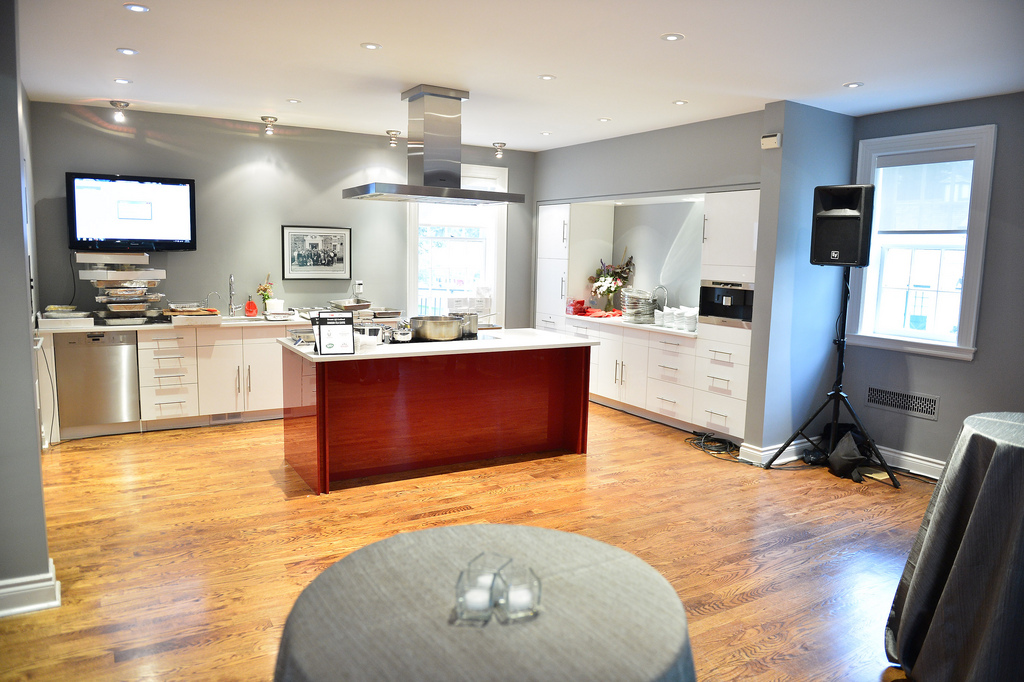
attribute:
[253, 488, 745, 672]
table — gray 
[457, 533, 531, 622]
candles — white 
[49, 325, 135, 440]
dishwasher — silver 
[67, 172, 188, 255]
screen — large 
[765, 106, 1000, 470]
wall — grey 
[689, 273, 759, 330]
microwave — built in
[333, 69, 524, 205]
fan — exhaust, over stove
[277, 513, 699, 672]
cloth — grey 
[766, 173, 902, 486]
speaker — black 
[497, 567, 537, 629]
holder — square 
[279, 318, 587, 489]
island — wood , marble 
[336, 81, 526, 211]
vent — silver 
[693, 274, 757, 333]
microwave — silver 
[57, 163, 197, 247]
screen — black 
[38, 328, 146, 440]
washer — silver 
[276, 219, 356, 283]
painting — black , white 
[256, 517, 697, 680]
table — round, grey 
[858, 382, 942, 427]
wall — grey 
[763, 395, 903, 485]
stand — black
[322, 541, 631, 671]
table — round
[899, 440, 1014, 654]
tablecloth — grey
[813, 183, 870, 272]
speaker — black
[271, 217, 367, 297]
frame — black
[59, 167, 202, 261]
tv — flat screen